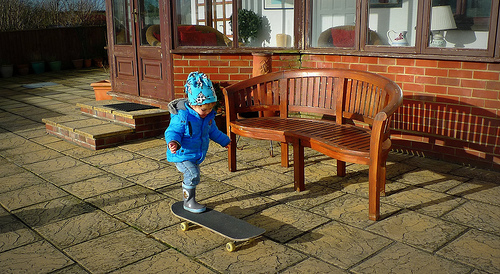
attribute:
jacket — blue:
[154, 87, 268, 221]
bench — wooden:
[215, 64, 407, 224]